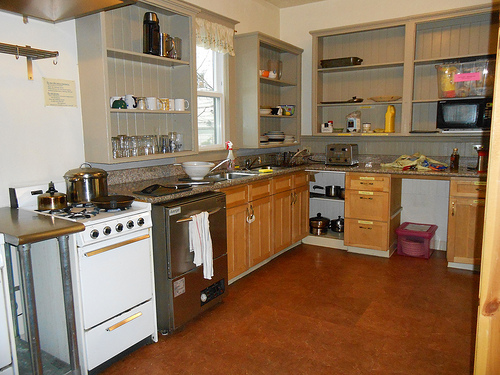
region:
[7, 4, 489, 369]
photograph of a kitchen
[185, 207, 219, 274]
white towels hanging on appliance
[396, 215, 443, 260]
plastic bin with a pink lid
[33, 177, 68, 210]
silver tea pot on top of stove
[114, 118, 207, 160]
clear glasses stacked on a shelf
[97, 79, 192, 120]
coffee mugs on a shelf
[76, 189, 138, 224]
black frying pan on top of stove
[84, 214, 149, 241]
five knobs on the front of the stove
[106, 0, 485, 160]
kitchen cabinets with no doors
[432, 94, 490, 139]
black microwave on shelf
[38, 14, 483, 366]
this is a kitchen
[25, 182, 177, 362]
this is a stove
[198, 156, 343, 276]
brown lower kitchen cabinets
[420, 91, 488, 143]
black microwave on shelf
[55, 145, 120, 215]
silver pot on stove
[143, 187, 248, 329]
this is a dishwasher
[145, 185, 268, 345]
the dishwasher is stainless steel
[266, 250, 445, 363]
dark brown kitchen floor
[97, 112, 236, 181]
glasses on kitchen shelff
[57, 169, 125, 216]
a pot in a kitchen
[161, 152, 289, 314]
a dish washer in a kitchen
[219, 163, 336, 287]
cabinet in a kitchen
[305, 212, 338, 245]
a pot in a kitchen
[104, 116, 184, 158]
glass in a kitchen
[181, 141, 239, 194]
a bowl in a kitchen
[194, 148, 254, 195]
a sink in a kitchen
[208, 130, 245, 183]
a fossett in a kitchen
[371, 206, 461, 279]
a pink container on the floor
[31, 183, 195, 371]
a white oven in the kitchen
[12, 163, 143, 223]
silver pans on top of a oven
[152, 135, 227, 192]
a white bowl on the counter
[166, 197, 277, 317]
a white dish towel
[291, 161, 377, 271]
a cabinet with pots and pans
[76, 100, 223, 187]
glasses on a shelf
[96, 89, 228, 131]
coffee mugs on a shelf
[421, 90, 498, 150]
a black microwave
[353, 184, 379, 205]
a handle on a drawer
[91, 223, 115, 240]
knobs on a stove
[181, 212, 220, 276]
a towl hanging from the handle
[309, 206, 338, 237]
pots on a shelf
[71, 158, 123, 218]
pots on the stove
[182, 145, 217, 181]
a bowl on the counter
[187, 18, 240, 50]
curtains above the window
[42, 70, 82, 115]
a paper on the wall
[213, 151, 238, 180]
a faucet on the sink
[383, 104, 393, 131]
yellow jug on shelf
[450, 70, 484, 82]
pink label on container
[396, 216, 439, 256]
clear pink storage container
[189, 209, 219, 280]
white dish towel on rack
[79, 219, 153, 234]
silver and black knobs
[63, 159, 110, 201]
large silver cooker on stove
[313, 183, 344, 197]
small silver cooker in cabinet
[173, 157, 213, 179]
large white bowl on counter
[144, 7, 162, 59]
tall dark thermos on shelf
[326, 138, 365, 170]
large silver toaster on cabinet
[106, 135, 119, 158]
glass on the wooden shelf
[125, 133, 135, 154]
glass on the wooden shelf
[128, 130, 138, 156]
glass on the wooden shelf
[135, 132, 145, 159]
glass on the wooden shelf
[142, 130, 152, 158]
glass on the wooden shelf